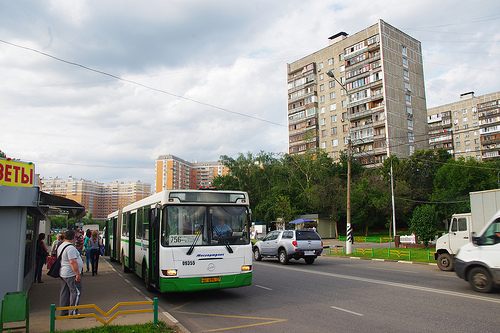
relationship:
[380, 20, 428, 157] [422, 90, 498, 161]
wall on building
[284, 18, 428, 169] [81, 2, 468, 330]
building in city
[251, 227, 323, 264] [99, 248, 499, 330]
car on street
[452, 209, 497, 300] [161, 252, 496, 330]
car on street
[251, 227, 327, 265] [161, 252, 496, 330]
car on street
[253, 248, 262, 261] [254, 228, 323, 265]
tire has vehicle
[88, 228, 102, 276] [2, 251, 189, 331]
person on sidewalk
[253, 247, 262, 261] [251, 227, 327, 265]
tire on car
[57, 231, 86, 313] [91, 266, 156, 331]
person standing on sidewalk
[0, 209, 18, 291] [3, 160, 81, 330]
wall on building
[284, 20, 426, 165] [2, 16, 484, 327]
building standing in city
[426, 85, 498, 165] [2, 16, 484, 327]
building standing in city